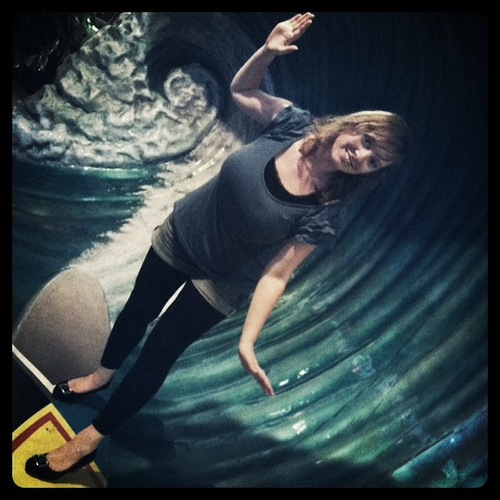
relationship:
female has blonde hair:
[24, 11, 414, 481] [298, 109, 410, 203]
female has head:
[24, 11, 414, 481] [330, 109, 404, 176]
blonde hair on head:
[298, 109, 410, 203] [330, 109, 404, 176]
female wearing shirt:
[24, 11, 414, 481] [142, 101, 376, 313]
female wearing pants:
[24, 11, 414, 481] [91, 244, 226, 438]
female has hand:
[24, 11, 414, 481] [262, 12, 316, 54]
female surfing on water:
[24, 11, 414, 481] [55, 30, 225, 221]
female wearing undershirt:
[24, 11, 414, 481] [264, 156, 324, 207]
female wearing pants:
[24, 11, 414, 481] [87, 290, 190, 466]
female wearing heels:
[24, 11, 414, 481] [24, 444, 99, 481]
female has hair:
[24, 11, 414, 481] [296, 108, 411, 181]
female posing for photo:
[24, 11, 414, 481] [7, 5, 494, 492]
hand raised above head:
[265, 8, 314, 53] [328, 109, 412, 173]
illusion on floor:
[13, 159, 479, 499] [19, 147, 433, 487]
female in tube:
[24, 11, 414, 481] [9, 6, 484, 486]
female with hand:
[24, 11, 414, 481] [237, 346, 273, 399]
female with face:
[24, 11, 414, 481] [331, 134, 388, 174]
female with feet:
[24, 11, 414, 481] [26, 377, 111, 480]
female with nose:
[24, 11, 414, 481] [351, 147, 373, 164]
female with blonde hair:
[24, 11, 414, 481] [303, 109, 409, 154]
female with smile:
[24, 11, 414, 481] [342, 145, 354, 170]